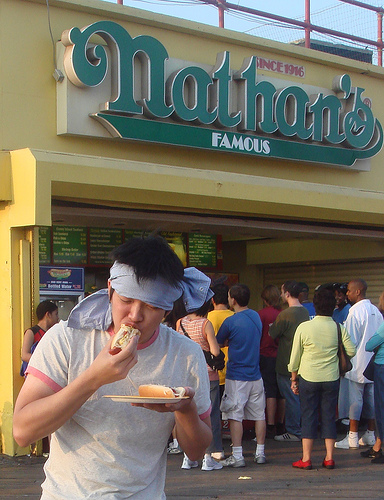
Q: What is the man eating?
A: Hotdog.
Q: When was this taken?
A: Daytime.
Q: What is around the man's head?
A: Headband.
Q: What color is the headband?
A: Blue.